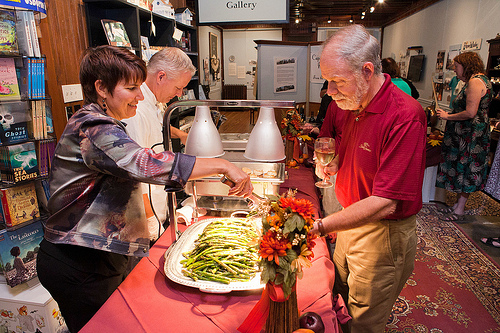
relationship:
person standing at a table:
[34, 42, 252, 332] [80, 132, 354, 332]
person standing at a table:
[122, 44, 199, 246] [80, 132, 354, 332]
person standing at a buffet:
[34, 42, 252, 332] [157, 129, 290, 302]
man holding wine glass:
[307, 20, 430, 332] [312, 134, 341, 193]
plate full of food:
[162, 205, 266, 298] [179, 220, 261, 286]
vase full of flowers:
[263, 268, 300, 333] [256, 193, 319, 294]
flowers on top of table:
[256, 193, 319, 294] [80, 132, 354, 332]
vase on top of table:
[263, 268, 300, 333] [80, 132, 354, 332]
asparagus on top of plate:
[190, 266, 231, 284] [162, 205, 266, 298]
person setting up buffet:
[122, 44, 199, 246] [157, 129, 290, 302]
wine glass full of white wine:
[312, 134, 341, 193] [317, 147, 337, 168]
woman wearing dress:
[433, 49, 495, 227] [435, 73, 493, 198]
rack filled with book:
[2, 95, 48, 103] [28, 56, 35, 101]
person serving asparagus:
[34, 42, 252, 332] [190, 266, 231, 284]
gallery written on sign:
[224, 1, 260, 12] [194, 0, 293, 26]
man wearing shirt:
[307, 20, 430, 332] [334, 72, 429, 222]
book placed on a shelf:
[10, 144, 39, 184] [2, 172, 56, 186]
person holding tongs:
[34, 42, 252, 332] [221, 169, 271, 208]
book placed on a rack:
[28, 56, 35, 101] [2, 95, 48, 103]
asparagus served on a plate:
[204, 247, 242, 274] [162, 205, 266, 298]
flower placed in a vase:
[303, 230, 317, 263] [263, 268, 300, 333]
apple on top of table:
[298, 308, 324, 332] [80, 132, 354, 332]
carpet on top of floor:
[382, 205, 500, 332] [206, 110, 499, 332]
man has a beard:
[307, 20, 430, 332] [333, 73, 371, 114]